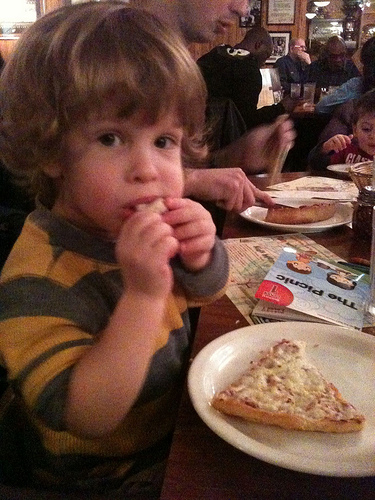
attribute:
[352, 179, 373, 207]
top — metal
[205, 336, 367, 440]
pizza — sliced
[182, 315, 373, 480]
plate — dinner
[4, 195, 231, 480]
sweater — striped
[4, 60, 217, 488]
young kid — eating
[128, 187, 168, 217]
piece of food — small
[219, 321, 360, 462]
cheese pizza — slice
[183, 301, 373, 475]
white plate — ceramic, round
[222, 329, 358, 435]
slice of pizza — small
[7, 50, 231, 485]
little boy — blond, eating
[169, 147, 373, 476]
wooden table — rectangular, brown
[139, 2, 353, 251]
man — reading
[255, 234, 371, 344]
coloring book — children's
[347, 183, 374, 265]
metal shaker — glass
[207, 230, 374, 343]
standing menus — table, dessert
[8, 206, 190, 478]
grey shirt — yellow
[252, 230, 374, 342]
childs book — child's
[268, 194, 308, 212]
plastic knife — white, dinner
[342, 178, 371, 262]
glass shaker — metal, pepper